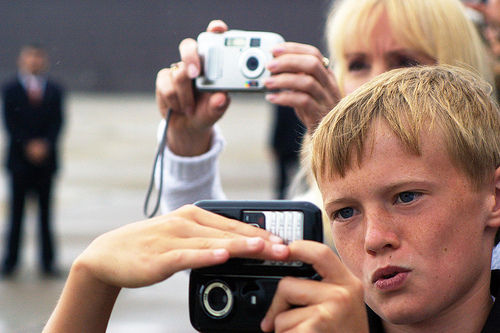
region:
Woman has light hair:
[322, 2, 497, 91]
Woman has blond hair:
[326, 2, 496, 90]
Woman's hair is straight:
[333, 0, 497, 86]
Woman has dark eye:
[338, 52, 376, 79]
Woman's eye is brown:
[341, 59, 383, 77]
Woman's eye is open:
[340, 57, 369, 74]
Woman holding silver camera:
[165, 15, 309, 90]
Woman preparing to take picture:
[162, 15, 312, 108]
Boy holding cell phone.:
[171, 194, 347, 331]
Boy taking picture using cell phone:
[104, 164, 334, 331]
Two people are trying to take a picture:
[41, 8, 490, 330]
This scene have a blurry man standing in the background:
[1, 28, 74, 285]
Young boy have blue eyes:
[311, 61, 498, 329]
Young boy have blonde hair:
[306, 68, 494, 327]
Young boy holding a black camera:
[5, 68, 495, 325]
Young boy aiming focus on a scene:
[0, 58, 495, 329]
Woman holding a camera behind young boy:
[105, 2, 496, 122]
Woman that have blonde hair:
[310, 0, 497, 86]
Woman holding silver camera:
[152, 8, 492, 193]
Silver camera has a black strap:
[138, 8, 314, 209]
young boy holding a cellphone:
[27, 54, 497, 331]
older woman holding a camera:
[134, 1, 497, 205]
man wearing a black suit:
[1, 36, 78, 281]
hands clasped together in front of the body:
[22, 136, 52, 164]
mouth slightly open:
[366, 261, 413, 288]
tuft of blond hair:
[336, 114, 377, 141]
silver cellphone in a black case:
[171, 192, 333, 332]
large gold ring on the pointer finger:
[313, 51, 330, 68]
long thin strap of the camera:
[136, 102, 175, 217]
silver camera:
[181, 28, 300, 103]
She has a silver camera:
[175, 10, 295, 104]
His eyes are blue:
[313, 152, 430, 230]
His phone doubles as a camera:
[156, 167, 354, 331]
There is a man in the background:
[12, 30, 96, 284]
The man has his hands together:
[6, 105, 66, 189]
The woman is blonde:
[235, 1, 499, 152]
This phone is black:
[156, 168, 340, 325]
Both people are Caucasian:
[98, 5, 492, 319]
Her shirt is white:
[128, 112, 256, 206]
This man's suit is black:
[5, 70, 83, 285]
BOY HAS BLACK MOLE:
[439, 238, 461, 282]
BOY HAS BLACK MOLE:
[439, 233, 449, 260]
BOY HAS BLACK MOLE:
[439, 241, 458, 265]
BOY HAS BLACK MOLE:
[444, 243, 454, 259]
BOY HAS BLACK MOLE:
[439, 246, 450, 259]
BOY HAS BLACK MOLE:
[436, 250, 459, 251]